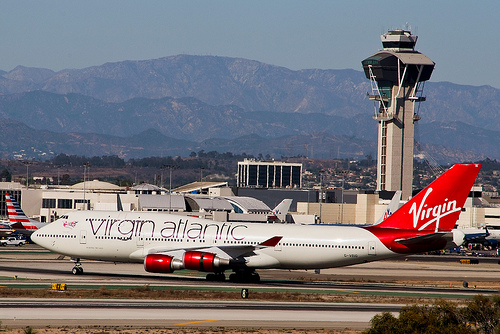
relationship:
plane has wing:
[26, 163, 492, 288] [136, 238, 268, 273]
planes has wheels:
[14, 157, 499, 277] [68, 255, 262, 284]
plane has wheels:
[26, 163, 492, 288] [213, 264, 256, 281]